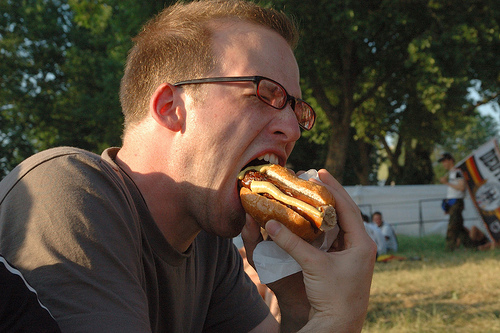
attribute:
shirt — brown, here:
[6, 118, 312, 333]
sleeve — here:
[4, 136, 160, 319]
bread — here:
[255, 153, 354, 193]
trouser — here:
[442, 210, 468, 239]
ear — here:
[146, 77, 182, 146]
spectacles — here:
[183, 46, 339, 111]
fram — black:
[179, 63, 253, 101]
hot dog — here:
[254, 156, 339, 239]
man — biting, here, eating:
[44, 6, 406, 328]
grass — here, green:
[402, 241, 447, 297]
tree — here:
[306, 18, 481, 283]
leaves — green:
[311, 15, 394, 72]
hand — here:
[255, 164, 406, 317]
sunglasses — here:
[235, 46, 343, 131]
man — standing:
[427, 114, 484, 263]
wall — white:
[376, 181, 453, 239]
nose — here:
[261, 105, 313, 146]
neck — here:
[113, 145, 190, 250]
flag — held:
[451, 134, 499, 219]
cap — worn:
[434, 140, 457, 163]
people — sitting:
[350, 193, 436, 291]